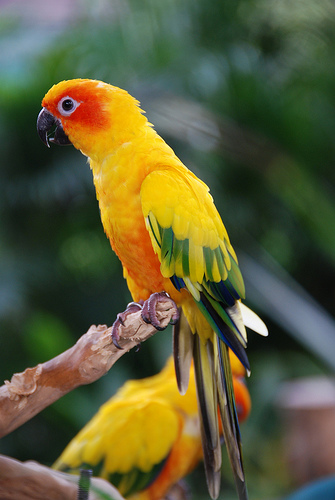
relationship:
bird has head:
[36, 75, 271, 493] [34, 78, 151, 161]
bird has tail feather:
[36, 75, 271, 493] [191, 324, 227, 497]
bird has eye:
[36, 75, 271, 493] [57, 93, 84, 119]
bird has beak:
[36, 75, 271, 493] [33, 108, 71, 155]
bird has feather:
[36, 75, 271, 493] [239, 295, 272, 340]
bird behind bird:
[49, 335, 253, 498] [36, 75, 271, 493]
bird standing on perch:
[36, 75, 271, 493] [1, 291, 174, 446]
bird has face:
[49, 335, 253, 498] [224, 351, 250, 396]